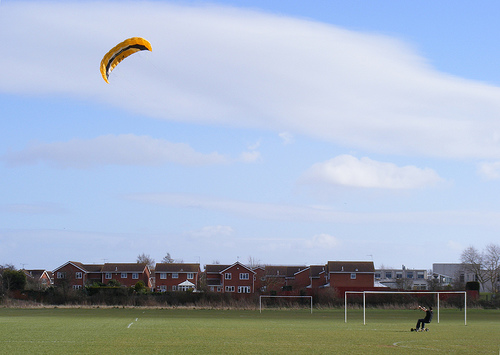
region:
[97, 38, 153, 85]
A yellow and black kite.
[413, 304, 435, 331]
A man in mostly black controlling a kite.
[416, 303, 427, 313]
Extended arms of a man controlling a kite.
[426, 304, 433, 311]
Head of a man controlling a kite.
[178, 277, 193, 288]
A bright white small roof on the front of a building.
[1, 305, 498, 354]
A green field a man is flying kites in.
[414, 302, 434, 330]
A man leaning back in mostly black flying a kite.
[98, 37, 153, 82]
A yellow kite with a black stripe on it.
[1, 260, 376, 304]
All the red brick houses.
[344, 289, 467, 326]
White metal poles around a guy flying a kite.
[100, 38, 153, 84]
Yellow and black kite in the sky.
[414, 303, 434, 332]
A man leaned back in mostly black.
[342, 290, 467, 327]
Four white bars around a man.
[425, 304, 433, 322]
Upper half of a man, chest up.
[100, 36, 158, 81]
A large yellow and black kite in the sky.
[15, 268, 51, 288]
Furthest left roof.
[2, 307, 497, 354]
Green grass field.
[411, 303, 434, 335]
A man in mostly black.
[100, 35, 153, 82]
Yellow kite with black on it.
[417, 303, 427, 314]
Arms on a man.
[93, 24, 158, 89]
this looks like a paragliding sail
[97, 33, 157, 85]
this paragliding sail is yellow and black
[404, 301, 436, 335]
this guy is about to take off parasailing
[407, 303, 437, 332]
this paragliding guy is wearing a black top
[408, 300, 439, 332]
this paragliding guy is wearing black pants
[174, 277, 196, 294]
there is a white gazebo in the distance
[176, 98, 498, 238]
the day is partly cloudy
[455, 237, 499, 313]
it is winter time, there are trees with no leaves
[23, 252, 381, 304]
a row of residences in the distance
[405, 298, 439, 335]
this guy is strapped into some kind of ski thing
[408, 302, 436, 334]
man flying a kite in a large field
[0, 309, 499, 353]
large green grassy field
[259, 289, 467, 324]
white bars on the field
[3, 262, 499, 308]
row of trees and bushes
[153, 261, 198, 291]
red brick building with a white lower roof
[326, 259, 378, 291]
red building with only one small window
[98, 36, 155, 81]
yellow crescent-shaped kite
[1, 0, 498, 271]
vast blue sky with faint white clouds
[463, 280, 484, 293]
black opening in a gray tunnel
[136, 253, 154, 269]
bare tre above the roof of a building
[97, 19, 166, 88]
yellow kite in the sky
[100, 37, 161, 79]
stripe on the kite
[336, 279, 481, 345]
soccer goals in the grass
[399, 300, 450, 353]
man is holding string to kite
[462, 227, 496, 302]
trees have no leaves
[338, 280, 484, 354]
soccer goals are white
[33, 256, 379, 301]
houses by soccer fields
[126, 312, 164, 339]
one line on grass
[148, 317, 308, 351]
soccer fields are light green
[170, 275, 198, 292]
white roof on building